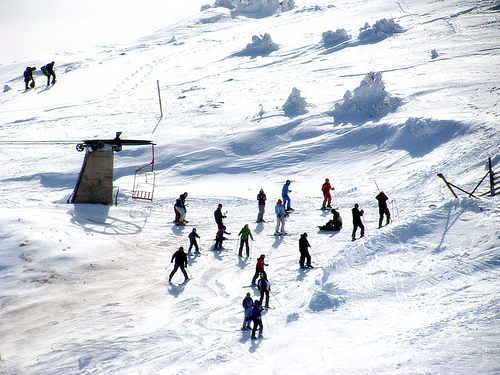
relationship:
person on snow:
[168, 247, 189, 283] [0, 3, 499, 373]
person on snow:
[298, 232, 314, 269] [0, 3, 499, 373]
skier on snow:
[256, 187, 269, 223] [0, 3, 499, 373]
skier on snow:
[320, 177, 336, 213] [0, 3, 499, 373]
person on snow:
[213, 203, 231, 235] [0, 3, 499, 373]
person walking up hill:
[40, 58, 58, 87] [0, 1, 498, 371]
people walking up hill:
[23, 66, 37, 91] [0, 1, 498, 371]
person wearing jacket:
[236, 222, 256, 259] [235, 230, 260, 240]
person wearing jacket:
[237, 224, 254, 258] [234, 228, 251, 236]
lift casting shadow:
[120, 147, 157, 211] [62, 200, 152, 237]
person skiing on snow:
[297, 228, 316, 273] [0, 3, 499, 373]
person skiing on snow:
[164, 244, 195, 287] [0, 3, 499, 373]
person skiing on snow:
[212, 204, 231, 237] [0, 3, 499, 373]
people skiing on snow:
[374, 191, 390, 229] [0, 3, 499, 373]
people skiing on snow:
[351, 204, 364, 242] [0, 3, 499, 373]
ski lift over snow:
[1, 134, 161, 210] [0, 3, 499, 373]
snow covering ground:
[0, 3, 499, 373] [0, 2, 497, 373]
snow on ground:
[0, 3, 499, 373] [23, 51, 473, 371]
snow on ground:
[0, 3, 499, 373] [15, 37, 492, 373]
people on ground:
[163, 166, 399, 343] [391, 132, 428, 165]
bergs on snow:
[277, 65, 401, 125] [352, 105, 426, 147]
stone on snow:
[65, 136, 126, 201] [320, 25, 432, 138]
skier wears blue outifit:
[239, 292, 254, 338] [241, 296, 253, 328]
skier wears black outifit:
[239, 292, 254, 338] [243, 299, 253, 321]